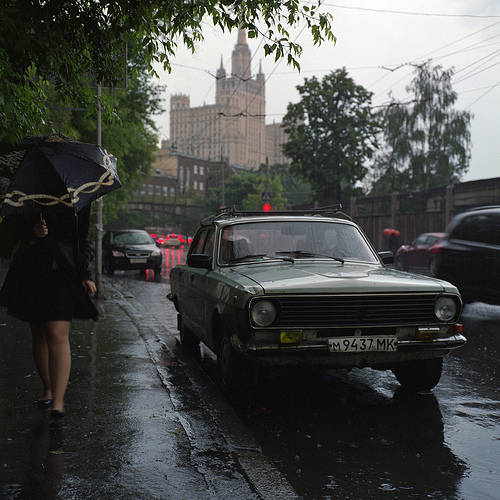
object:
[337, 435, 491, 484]
street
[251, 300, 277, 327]
headlights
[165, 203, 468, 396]
car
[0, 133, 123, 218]
umbrella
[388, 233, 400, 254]
person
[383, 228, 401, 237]
umbrella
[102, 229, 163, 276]
car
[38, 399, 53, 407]
shoe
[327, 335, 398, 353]
license plate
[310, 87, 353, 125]
leaves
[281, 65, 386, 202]
tree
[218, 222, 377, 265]
window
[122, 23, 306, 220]
building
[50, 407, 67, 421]
flat shoes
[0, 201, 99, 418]
lady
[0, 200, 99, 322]
dress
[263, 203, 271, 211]
traffic light